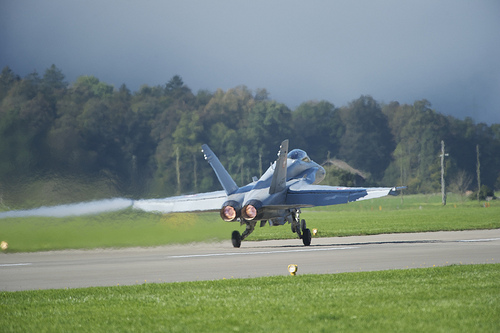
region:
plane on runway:
[112, 126, 394, 248]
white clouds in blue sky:
[37, 0, 96, 48]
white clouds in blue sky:
[413, 49, 460, 81]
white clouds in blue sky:
[343, 28, 383, 75]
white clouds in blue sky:
[202, 32, 245, 71]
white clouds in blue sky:
[273, 32, 323, 83]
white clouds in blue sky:
[163, 21, 216, 63]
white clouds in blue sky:
[102, 9, 161, 61]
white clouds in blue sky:
[215, 22, 262, 62]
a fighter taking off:
[118, 134, 408, 250]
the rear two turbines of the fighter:
[217, 200, 262, 225]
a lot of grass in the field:
[171, 294, 482, 316]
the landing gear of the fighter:
[228, 223, 313, 245]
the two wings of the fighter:
[147, 188, 384, 210]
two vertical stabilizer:
[194, 139, 291, 191]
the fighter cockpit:
[288, 148, 304, 163]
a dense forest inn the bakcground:
[10, 88, 325, 143]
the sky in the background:
[122, 30, 457, 72]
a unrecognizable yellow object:
[288, 265, 296, 274]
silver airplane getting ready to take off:
[189, 148, 479, 280]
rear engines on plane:
[223, 196, 274, 226]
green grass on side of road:
[351, 291, 467, 326]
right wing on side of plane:
[314, 181, 405, 202]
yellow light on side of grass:
[274, 257, 319, 289]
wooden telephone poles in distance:
[432, 130, 471, 203]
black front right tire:
[299, 226, 327, 255]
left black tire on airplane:
[215, 228, 263, 264]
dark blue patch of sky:
[28, 26, 68, 59]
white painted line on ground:
[449, 226, 494, 248]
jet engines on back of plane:
[216, 200, 266, 245]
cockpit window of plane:
[281, 134, 309, 175]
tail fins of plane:
[184, 132, 304, 197]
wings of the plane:
[125, 180, 403, 207]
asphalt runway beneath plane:
[6, 226, 473, 281]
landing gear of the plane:
[219, 219, 321, 256]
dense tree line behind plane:
[14, 56, 473, 191]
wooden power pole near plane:
[411, 128, 478, 205]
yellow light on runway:
[265, 256, 308, 283]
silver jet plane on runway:
[126, 82, 428, 260]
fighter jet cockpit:
[286, 148, 304, 159]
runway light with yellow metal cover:
[287, 263, 297, 275]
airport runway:
[0, 233, 363, 292]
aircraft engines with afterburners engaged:
[221, 200, 261, 221]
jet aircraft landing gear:
[230, 218, 312, 246]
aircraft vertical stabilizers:
[198, 137, 289, 194]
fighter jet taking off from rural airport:
[2, 0, 497, 331]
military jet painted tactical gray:
[127, 139, 405, 247]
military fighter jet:
[127, 140, 389, 250]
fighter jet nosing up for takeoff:
[5, 141, 495, 288]